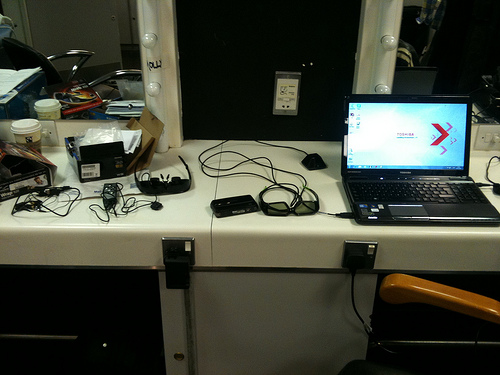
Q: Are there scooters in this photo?
A: No, there are no scooters.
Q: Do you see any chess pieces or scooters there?
A: No, there are no scooters or chess pieces.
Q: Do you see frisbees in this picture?
A: No, there are no frisbees.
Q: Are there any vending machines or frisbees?
A: No, there are no frisbees or vending machines.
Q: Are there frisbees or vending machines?
A: No, there are no frisbees or vending machines.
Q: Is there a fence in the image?
A: No, there are no fences.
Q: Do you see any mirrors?
A: Yes, there is a mirror.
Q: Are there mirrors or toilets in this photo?
A: Yes, there is a mirror.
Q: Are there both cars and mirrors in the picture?
A: No, there is a mirror but no cars.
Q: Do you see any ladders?
A: No, there are no ladders.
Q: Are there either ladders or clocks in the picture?
A: No, there are no ladders or clocks.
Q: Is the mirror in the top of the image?
A: Yes, the mirror is in the top of the image.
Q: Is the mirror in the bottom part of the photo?
A: No, the mirror is in the top of the image.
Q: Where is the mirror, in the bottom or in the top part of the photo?
A: The mirror is in the top of the image.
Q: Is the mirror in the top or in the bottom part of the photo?
A: The mirror is in the top of the image.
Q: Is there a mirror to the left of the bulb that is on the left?
A: Yes, there is a mirror to the left of the light bulb.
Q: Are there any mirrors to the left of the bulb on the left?
A: Yes, there is a mirror to the left of the light bulb.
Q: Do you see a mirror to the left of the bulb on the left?
A: Yes, there is a mirror to the left of the light bulb.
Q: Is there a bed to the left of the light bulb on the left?
A: No, there is a mirror to the left of the light bulb.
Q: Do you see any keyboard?
A: Yes, there is a keyboard.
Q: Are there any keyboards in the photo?
A: Yes, there is a keyboard.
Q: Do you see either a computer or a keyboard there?
A: Yes, there is a keyboard.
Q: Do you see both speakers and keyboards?
A: No, there is a keyboard but no speakers.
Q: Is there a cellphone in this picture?
A: No, there are no cell phones.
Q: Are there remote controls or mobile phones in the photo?
A: No, there are no mobile phones or remote controls.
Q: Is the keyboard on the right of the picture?
A: Yes, the keyboard is on the right of the image.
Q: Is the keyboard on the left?
A: No, the keyboard is on the right of the image.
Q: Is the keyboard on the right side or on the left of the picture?
A: The keyboard is on the right of the image.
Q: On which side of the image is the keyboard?
A: The keyboard is on the right of the image.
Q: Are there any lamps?
A: No, there are no lamps.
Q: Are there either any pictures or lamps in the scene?
A: No, there are no lamps or pictures.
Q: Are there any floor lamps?
A: No, there are no floor lamps.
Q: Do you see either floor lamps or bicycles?
A: No, there are no floor lamps or bicycles.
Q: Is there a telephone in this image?
A: No, there are no phones.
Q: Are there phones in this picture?
A: No, there are no phones.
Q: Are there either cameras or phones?
A: No, there are no phones or cameras.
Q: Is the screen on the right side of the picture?
A: Yes, the screen is on the right of the image.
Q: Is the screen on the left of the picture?
A: No, the screen is on the right of the image.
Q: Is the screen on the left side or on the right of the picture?
A: The screen is on the right of the image.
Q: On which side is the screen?
A: The screen is on the right of the image.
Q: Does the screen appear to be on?
A: Yes, the screen is on.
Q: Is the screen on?
A: Yes, the screen is on.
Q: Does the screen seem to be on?
A: Yes, the screen is on.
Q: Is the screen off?
A: No, the screen is on.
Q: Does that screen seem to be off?
A: No, the screen is on.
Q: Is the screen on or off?
A: The screen is on.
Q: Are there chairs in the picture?
A: Yes, there is a chair.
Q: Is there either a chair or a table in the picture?
A: Yes, there is a chair.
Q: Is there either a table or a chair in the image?
A: Yes, there is a chair.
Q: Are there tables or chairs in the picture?
A: Yes, there is a chair.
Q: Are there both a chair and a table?
A: Yes, there are both a chair and a table.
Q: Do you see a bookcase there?
A: No, there are no bookcases.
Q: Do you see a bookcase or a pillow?
A: No, there are no bookcases or pillows.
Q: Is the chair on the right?
A: Yes, the chair is on the right of the image.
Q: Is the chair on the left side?
A: No, the chair is on the right of the image.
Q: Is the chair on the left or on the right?
A: The chair is on the right of the image.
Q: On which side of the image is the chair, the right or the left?
A: The chair is on the right of the image.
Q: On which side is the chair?
A: The chair is on the right of the image.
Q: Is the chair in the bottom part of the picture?
A: Yes, the chair is in the bottom of the image.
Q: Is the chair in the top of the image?
A: No, the chair is in the bottom of the image.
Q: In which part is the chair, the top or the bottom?
A: The chair is in the bottom of the image.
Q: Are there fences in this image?
A: No, there are no fences.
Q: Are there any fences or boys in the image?
A: No, there are no fences or boys.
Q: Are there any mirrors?
A: Yes, there is a mirror.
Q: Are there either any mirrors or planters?
A: Yes, there is a mirror.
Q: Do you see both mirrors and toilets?
A: No, there is a mirror but no toilets.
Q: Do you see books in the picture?
A: No, there are no books.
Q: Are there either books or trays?
A: No, there are no books or trays.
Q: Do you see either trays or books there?
A: No, there are no books or trays.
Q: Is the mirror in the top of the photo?
A: Yes, the mirror is in the top of the image.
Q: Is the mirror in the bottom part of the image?
A: No, the mirror is in the top of the image.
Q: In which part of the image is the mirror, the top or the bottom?
A: The mirror is in the top of the image.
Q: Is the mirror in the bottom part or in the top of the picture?
A: The mirror is in the top of the image.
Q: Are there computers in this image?
A: Yes, there is a computer.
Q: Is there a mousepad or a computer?
A: Yes, there is a computer.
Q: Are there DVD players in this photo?
A: No, there are no DVD players.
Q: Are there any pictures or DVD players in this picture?
A: No, there are no DVD players or pictures.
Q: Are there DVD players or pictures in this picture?
A: No, there are no DVD players or pictures.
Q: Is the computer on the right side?
A: Yes, the computer is on the right of the image.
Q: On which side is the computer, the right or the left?
A: The computer is on the right of the image.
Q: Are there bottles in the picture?
A: No, there are no bottles.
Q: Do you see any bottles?
A: No, there are no bottles.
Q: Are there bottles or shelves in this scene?
A: No, there are no bottles or shelves.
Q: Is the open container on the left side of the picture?
A: Yes, the box is on the left of the image.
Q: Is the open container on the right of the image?
A: No, the box is on the left of the image.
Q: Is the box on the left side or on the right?
A: The box is on the left of the image.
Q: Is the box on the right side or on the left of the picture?
A: The box is on the left of the image.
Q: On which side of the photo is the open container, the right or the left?
A: The box is on the left of the image.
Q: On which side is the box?
A: The box is on the left of the image.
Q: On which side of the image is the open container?
A: The box is on the left of the image.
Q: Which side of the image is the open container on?
A: The box is on the left of the image.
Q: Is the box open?
A: Yes, the box is open.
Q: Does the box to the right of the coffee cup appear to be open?
A: Yes, the box is open.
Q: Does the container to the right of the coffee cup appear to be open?
A: Yes, the box is open.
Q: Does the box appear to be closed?
A: No, the box is open.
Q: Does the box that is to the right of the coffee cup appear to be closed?
A: No, the box is open.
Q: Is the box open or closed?
A: The box is open.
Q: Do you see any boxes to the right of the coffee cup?
A: Yes, there is a box to the right of the coffee cup.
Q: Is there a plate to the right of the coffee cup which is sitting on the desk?
A: No, there is a box to the right of the coffee cup.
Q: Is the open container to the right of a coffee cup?
A: Yes, the box is to the right of a coffee cup.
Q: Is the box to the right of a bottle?
A: No, the box is to the right of a coffee cup.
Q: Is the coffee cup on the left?
A: Yes, the coffee cup is on the left of the image.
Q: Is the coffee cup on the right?
A: No, the coffee cup is on the left of the image.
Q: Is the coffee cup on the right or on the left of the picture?
A: The coffee cup is on the left of the image.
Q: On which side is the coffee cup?
A: The coffee cup is on the left of the image.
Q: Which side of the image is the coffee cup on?
A: The coffee cup is on the left of the image.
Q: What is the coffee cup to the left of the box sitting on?
A: The coffee cup is sitting on the desk.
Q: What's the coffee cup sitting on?
A: The coffee cup is sitting on the desk.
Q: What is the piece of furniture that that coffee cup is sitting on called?
A: The piece of furniture is a desk.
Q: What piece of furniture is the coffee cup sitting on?
A: The coffee cup is sitting on the desk.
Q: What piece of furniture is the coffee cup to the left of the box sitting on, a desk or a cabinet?
A: The coffee cup is sitting on a desk.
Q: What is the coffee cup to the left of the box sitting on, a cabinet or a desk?
A: The coffee cup is sitting on a desk.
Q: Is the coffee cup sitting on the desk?
A: Yes, the coffee cup is sitting on the desk.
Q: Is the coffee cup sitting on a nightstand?
A: No, the coffee cup is sitting on the desk.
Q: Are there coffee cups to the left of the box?
A: Yes, there is a coffee cup to the left of the box.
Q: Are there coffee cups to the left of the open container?
A: Yes, there is a coffee cup to the left of the box.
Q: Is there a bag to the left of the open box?
A: No, there is a coffee cup to the left of the box.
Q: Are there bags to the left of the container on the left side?
A: No, there is a coffee cup to the left of the box.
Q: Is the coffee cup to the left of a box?
A: Yes, the coffee cup is to the left of a box.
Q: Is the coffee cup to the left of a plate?
A: No, the coffee cup is to the left of a box.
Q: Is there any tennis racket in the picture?
A: No, there are no rackets.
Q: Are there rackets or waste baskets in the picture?
A: No, there are no rackets or waste baskets.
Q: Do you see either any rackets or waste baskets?
A: No, there are no rackets or waste baskets.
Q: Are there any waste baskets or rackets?
A: No, there are no rackets or waste baskets.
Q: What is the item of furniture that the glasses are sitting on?
A: The piece of furniture is a desk.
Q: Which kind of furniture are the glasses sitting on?
A: The glasses are sitting on the desk.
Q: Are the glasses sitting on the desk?
A: Yes, the glasses are sitting on the desk.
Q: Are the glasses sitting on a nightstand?
A: No, the glasses are sitting on the desk.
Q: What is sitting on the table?
A: The glasses are sitting on the table.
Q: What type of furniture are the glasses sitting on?
A: The glasses are sitting on the table.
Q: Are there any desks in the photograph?
A: Yes, there is a desk.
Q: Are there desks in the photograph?
A: Yes, there is a desk.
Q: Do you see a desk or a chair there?
A: Yes, there is a desk.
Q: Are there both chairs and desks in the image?
A: Yes, there are both a desk and a chair.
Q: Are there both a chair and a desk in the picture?
A: Yes, there are both a desk and a chair.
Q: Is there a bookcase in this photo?
A: No, there are no bookcases.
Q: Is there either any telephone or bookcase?
A: No, there are no bookcases or phones.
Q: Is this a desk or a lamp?
A: This is a desk.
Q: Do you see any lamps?
A: No, there are no lamps.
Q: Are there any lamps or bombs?
A: No, there are no lamps or bombs.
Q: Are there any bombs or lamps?
A: No, there are no lamps or bombs.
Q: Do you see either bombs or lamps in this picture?
A: No, there are no lamps or bombs.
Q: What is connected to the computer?
A: The wire is connected to the computer.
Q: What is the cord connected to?
A: The wire is connected to the computer.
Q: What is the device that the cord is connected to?
A: The device is a computer.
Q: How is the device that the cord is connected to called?
A: The device is a computer.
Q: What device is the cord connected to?
A: The cord is connected to the computer.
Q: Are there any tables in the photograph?
A: Yes, there is a table.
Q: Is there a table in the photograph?
A: Yes, there is a table.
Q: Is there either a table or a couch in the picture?
A: Yes, there is a table.